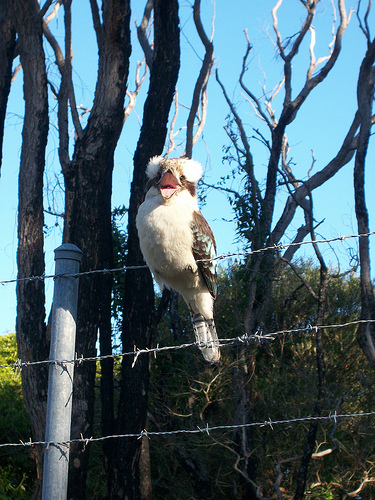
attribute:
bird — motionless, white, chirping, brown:
[136, 155, 224, 367]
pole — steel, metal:
[37, 242, 85, 499]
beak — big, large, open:
[154, 167, 183, 201]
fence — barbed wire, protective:
[0, 228, 375, 448]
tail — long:
[179, 290, 222, 365]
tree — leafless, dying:
[1, 0, 133, 499]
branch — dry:
[288, 0, 349, 116]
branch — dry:
[238, 23, 278, 133]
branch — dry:
[305, 146, 318, 182]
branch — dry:
[353, 1, 372, 50]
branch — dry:
[55, 0, 74, 175]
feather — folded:
[149, 269, 165, 313]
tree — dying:
[212, 4, 361, 459]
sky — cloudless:
[1, 4, 374, 338]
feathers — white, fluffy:
[178, 159, 205, 186]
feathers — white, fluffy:
[143, 154, 165, 183]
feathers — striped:
[190, 210, 219, 302]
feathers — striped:
[190, 303, 222, 367]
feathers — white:
[133, 187, 197, 286]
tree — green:
[1, 331, 54, 499]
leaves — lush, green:
[1, 334, 35, 498]